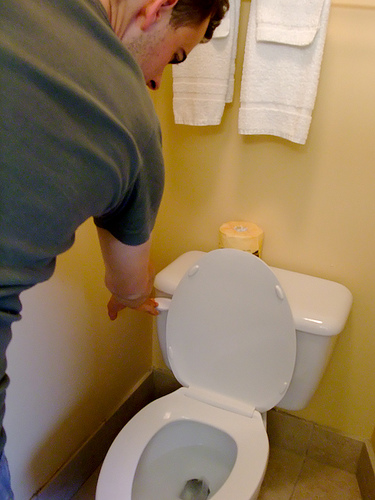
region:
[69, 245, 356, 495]
a white toilet in the bathroom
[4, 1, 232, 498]
a man standing in the bathroom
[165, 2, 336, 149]
white towels in the bathroom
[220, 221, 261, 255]
an extra roll of toilet paper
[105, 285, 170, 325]
a hand flushing the toilet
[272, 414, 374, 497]
the beige colored tile floor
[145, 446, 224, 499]
water in the bowl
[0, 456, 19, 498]
a pair blue jeans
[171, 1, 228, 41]
the man has brown hair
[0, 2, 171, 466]
the man has on a tshirt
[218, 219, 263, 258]
backup roll of toilet paper sits on the tank of the toilet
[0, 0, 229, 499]
a man flushing stinky toilet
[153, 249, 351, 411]
an older toilet tank can use up to 7 gallons of water with every flush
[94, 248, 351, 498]
this toilet is made of porcelain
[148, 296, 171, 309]
the toilet flushing handle is a dirty area of a bathroom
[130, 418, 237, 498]
the toilet bowel needs to be cleaned with bleach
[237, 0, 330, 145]
there are two bath towels and two wash cloths on the towel rack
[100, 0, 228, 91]
the man needs a shave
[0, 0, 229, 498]
the man is a plumber repairing a clogged toilet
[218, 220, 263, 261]
the toilet paper roll is wrapped in a yellow paper wrapper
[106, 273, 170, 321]
man is flushing a toilet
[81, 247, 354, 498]
toilet is white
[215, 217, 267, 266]
toilet paper is sitting on toilet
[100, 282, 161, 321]
man's right hand is pushing handle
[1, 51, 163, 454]
man's shirt is gray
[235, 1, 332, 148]
towels are white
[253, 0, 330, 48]
washcloths are white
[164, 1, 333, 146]
towels are hanging on the wall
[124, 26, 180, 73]
the man has a little facial hair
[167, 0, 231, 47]
the man's hair is brown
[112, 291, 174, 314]
a man's hand flushing the toilet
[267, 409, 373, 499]
the beige tile floor by the toilet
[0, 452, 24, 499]
A pair of blue jeans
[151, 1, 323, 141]
towels on the rack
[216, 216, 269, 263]
A roll of toilet paper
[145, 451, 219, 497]
Water in the toilet bowl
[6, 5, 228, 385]
a man by the toilet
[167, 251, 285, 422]
the lid for the toilet seat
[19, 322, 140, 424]
the wall in the bathroom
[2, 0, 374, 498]
A young man flushing the toilet.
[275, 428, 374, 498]
The stone tiled flooring.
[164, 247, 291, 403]
The lid of the toilet.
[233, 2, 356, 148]
A white cloth and towel.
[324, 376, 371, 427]
The mustard yellow walls.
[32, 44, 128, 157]
The man's dark blue shirt.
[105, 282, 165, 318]
The man's right hand.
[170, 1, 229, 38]
The man's dark brown hair.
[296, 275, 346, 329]
The white top of the commode.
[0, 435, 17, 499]
The man's blue jeans.